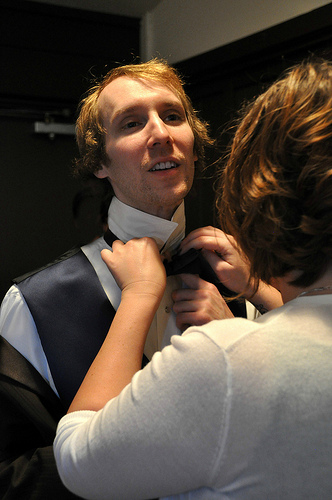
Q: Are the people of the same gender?
A: No, they are both male and female.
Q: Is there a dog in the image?
A: No, there are no dogs.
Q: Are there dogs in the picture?
A: No, there are no dogs.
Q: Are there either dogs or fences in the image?
A: No, there are no dogs or fences.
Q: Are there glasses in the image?
A: No, there are no glasses.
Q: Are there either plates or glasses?
A: No, there are no glasses or plates.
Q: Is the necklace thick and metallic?
A: No, the necklace is metallic but thin.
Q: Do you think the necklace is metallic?
A: Yes, the necklace is metallic.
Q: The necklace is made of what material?
A: The necklace is made of metal.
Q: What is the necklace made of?
A: The necklace is made of metal.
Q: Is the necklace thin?
A: Yes, the necklace is thin.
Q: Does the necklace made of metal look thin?
A: Yes, the necklace is thin.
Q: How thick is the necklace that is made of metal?
A: The necklace is thin.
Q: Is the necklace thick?
A: No, the necklace is thin.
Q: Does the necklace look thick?
A: No, the necklace is thin.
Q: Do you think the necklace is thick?
A: No, the necklace is thin.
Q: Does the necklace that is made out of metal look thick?
A: No, the necklace is thin.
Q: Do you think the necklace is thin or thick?
A: The necklace is thin.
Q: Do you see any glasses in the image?
A: No, there are no glasses.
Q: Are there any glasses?
A: No, there are no glasses.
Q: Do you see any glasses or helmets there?
A: No, there are no glasses or helmets.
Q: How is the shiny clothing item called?
A: The clothing item is a vest.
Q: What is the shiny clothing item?
A: The clothing item is a vest.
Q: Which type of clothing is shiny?
A: The clothing is a vest.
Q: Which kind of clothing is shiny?
A: The clothing is a vest.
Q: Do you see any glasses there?
A: No, there are no glasses.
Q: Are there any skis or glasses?
A: No, there are no glasses or skis.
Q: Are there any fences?
A: No, there are no fences.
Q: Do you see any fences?
A: No, there are no fences.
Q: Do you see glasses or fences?
A: No, there are no fences or glasses.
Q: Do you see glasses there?
A: No, there are no glasses.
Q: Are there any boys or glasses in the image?
A: No, there are no glasses or boys.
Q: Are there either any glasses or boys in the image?
A: No, there are no glasses or boys.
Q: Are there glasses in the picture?
A: No, there are no glasses.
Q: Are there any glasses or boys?
A: No, there are no glasses or boys.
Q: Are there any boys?
A: No, there are no boys.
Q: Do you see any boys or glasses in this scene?
A: No, there are no boys or glasses.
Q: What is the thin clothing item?
A: The clothing item is a shirt.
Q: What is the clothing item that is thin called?
A: The clothing item is a shirt.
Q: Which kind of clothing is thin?
A: The clothing is a shirt.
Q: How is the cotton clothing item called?
A: The clothing item is a shirt.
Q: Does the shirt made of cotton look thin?
A: Yes, the shirt is thin.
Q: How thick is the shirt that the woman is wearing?
A: The shirt is thin.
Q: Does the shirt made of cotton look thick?
A: No, the shirt is thin.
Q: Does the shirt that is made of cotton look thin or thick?
A: The shirt is thin.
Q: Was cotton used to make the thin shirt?
A: Yes, the shirt is made of cotton.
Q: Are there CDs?
A: No, there are no cds.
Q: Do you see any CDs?
A: No, there are no cds.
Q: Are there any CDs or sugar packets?
A: No, there are no CDs or sugar packets.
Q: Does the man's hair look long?
A: Yes, the hair is long.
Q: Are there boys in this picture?
A: No, there are no boys.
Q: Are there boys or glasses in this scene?
A: No, there are no boys or glasses.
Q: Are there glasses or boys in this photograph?
A: No, there are no boys or glasses.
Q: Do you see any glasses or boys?
A: No, there are no boys or glasses.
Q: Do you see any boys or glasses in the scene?
A: No, there are no boys or glasses.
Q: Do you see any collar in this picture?
A: Yes, there is a collar.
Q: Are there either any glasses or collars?
A: Yes, there is a collar.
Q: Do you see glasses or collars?
A: Yes, there is a collar.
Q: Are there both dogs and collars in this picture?
A: No, there is a collar but no dogs.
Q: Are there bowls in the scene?
A: No, there are no bowls.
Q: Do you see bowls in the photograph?
A: No, there are no bowls.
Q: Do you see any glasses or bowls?
A: No, there are no bowls or glasses.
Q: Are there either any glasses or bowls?
A: No, there are no bowls or glasses.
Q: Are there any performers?
A: No, there are no performers.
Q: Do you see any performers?
A: No, there are no performers.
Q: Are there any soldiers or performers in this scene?
A: No, there are no performers or soldiers.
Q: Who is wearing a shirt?
A: The man is wearing a shirt.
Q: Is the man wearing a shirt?
A: Yes, the man is wearing a shirt.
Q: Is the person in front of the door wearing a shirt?
A: Yes, the man is wearing a shirt.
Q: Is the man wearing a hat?
A: No, the man is wearing a shirt.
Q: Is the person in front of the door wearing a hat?
A: No, the man is wearing a shirt.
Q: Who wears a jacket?
A: The man wears a jacket.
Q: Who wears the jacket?
A: The man wears a jacket.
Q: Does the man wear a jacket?
A: Yes, the man wears a jacket.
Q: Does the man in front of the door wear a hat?
A: No, the man wears a jacket.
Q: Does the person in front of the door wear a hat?
A: No, the man wears a jacket.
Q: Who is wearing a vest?
A: The man is wearing a vest.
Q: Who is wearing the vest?
A: The man is wearing a vest.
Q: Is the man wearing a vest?
A: Yes, the man is wearing a vest.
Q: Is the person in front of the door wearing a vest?
A: Yes, the man is wearing a vest.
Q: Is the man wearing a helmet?
A: No, the man is wearing a vest.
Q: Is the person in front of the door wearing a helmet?
A: No, the man is wearing a vest.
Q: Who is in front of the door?
A: The man is in front of the door.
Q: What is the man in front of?
A: The man is in front of the door.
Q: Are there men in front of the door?
A: Yes, there is a man in front of the door.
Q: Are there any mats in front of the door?
A: No, there is a man in front of the door.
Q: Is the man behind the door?
A: No, the man is in front of the door.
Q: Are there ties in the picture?
A: Yes, there is a tie.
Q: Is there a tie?
A: Yes, there is a tie.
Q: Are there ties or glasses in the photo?
A: Yes, there is a tie.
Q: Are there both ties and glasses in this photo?
A: No, there is a tie but no glasses.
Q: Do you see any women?
A: Yes, there is a woman.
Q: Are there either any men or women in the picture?
A: Yes, there is a woman.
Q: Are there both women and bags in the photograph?
A: No, there is a woman but no bags.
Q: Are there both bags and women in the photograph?
A: No, there is a woman but no bags.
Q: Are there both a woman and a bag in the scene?
A: No, there is a woman but no bags.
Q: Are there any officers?
A: No, there are no officers.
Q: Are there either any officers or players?
A: No, there are no officers or players.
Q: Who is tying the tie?
A: The woman is tying the necktie.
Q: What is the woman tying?
A: The woman is tying the tie.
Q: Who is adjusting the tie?
A: The woman is adjusting the tie.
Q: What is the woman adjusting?
A: The woman is adjusting the tie.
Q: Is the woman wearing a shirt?
A: Yes, the woman is wearing a shirt.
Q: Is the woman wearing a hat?
A: No, the woman is wearing a shirt.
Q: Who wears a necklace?
A: The woman wears a necklace.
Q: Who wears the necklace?
A: The woman wears a necklace.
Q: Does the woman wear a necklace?
A: Yes, the woman wears a necklace.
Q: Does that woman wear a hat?
A: No, the woman wears a necklace.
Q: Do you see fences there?
A: No, there are no fences.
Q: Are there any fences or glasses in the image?
A: No, there are no fences or glasses.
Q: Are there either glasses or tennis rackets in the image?
A: No, there are no glasses or tennis rackets.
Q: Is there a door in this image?
A: Yes, there is a door.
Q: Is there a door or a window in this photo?
A: Yes, there is a door.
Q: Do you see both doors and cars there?
A: No, there is a door but no cars.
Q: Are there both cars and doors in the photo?
A: No, there is a door but no cars.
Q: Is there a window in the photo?
A: No, there are no windows.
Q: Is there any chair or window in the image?
A: No, there are no windows or chairs.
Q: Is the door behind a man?
A: Yes, the door is behind a man.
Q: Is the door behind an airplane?
A: No, the door is behind a man.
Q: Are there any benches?
A: No, there are no benches.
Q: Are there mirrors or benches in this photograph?
A: No, there are no benches or mirrors.